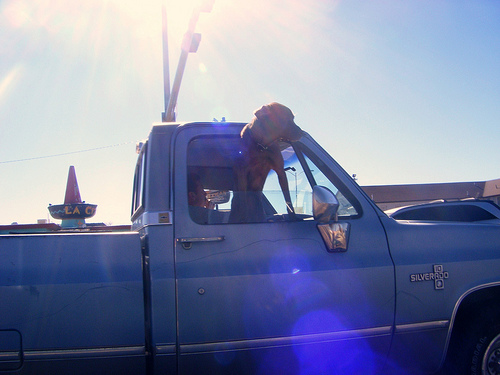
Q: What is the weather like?
A: It is cloudy.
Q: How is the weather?
A: It is cloudy.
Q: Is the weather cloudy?
A: Yes, it is cloudy.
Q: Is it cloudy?
A: Yes, it is cloudy.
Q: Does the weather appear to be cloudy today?
A: Yes, it is cloudy.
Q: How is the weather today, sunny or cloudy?
A: It is cloudy.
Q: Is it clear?
A: No, it is cloudy.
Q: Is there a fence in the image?
A: No, there are no fences.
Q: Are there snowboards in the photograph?
A: No, there are no snowboards.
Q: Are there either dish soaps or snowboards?
A: No, there are no snowboards or dish soaps.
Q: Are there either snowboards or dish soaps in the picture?
A: No, there are no snowboards or dish soaps.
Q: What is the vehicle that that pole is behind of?
A: The vehicle is a truck.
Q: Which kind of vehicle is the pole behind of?
A: The pole is behind the truck.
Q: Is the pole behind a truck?
A: Yes, the pole is behind a truck.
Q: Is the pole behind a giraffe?
A: No, the pole is behind a truck.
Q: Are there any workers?
A: No, there are no workers.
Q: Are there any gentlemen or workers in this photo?
A: No, there are no workers or gentlemen.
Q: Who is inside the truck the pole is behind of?
A: The driver is inside the truck.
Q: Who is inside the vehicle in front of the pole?
A: The driver is inside the truck.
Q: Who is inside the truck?
A: The driver is inside the truck.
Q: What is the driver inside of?
A: The driver is inside the truck.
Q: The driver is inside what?
A: The driver is inside the truck.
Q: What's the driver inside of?
A: The driver is inside the truck.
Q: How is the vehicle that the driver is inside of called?
A: The vehicle is a truck.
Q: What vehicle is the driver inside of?
A: The driver is inside the truck.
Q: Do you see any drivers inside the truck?
A: Yes, there is a driver inside the truck.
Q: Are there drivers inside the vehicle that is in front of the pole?
A: Yes, there is a driver inside the truck.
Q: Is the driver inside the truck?
A: Yes, the driver is inside the truck.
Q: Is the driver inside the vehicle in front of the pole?
A: Yes, the driver is inside the truck.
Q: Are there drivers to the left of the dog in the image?
A: Yes, there is a driver to the left of the dog.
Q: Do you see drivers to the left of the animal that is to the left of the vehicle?
A: Yes, there is a driver to the left of the dog.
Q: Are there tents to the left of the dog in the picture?
A: No, there is a driver to the left of the dog.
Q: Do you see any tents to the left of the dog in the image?
A: No, there is a driver to the left of the dog.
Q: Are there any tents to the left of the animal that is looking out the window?
A: No, there is a driver to the left of the dog.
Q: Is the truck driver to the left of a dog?
A: Yes, the driver is to the left of a dog.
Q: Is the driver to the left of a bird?
A: No, the driver is to the left of a dog.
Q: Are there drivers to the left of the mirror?
A: Yes, there is a driver to the left of the mirror.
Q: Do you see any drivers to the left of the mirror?
A: Yes, there is a driver to the left of the mirror.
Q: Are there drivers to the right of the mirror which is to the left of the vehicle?
A: No, the driver is to the left of the mirror.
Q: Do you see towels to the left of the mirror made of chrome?
A: No, there is a driver to the left of the mirror.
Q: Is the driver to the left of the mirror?
A: Yes, the driver is to the left of the mirror.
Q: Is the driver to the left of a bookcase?
A: No, the driver is to the left of the mirror.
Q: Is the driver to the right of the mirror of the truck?
A: No, the driver is to the left of the mirror.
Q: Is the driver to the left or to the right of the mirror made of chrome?
A: The driver is to the left of the mirror.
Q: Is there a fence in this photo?
A: No, there are no fences.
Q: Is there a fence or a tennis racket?
A: No, there are no fences or rackets.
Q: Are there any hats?
A: Yes, there is a hat.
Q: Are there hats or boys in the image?
A: Yes, there is a hat.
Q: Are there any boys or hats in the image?
A: Yes, there is a hat.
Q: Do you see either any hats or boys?
A: Yes, there is a hat.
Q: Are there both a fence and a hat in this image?
A: No, there is a hat but no fences.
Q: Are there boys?
A: No, there are no boys.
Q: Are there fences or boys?
A: No, there are no boys or fences.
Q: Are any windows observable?
A: Yes, there is a window.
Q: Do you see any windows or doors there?
A: Yes, there is a window.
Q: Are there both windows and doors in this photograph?
A: Yes, there are both a window and a door.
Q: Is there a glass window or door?
A: Yes, there is a glass window.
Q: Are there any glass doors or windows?
A: Yes, there is a glass window.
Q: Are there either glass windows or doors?
A: Yes, there is a glass window.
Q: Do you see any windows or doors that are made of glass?
A: Yes, the window is made of glass.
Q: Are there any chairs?
A: No, there are no chairs.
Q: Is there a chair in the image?
A: No, there are no chairs.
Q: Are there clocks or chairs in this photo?
A: No, there are no chairs or clocks.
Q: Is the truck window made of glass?
A: Yes, the window is made of glass.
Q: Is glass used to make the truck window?
A: Yes, the window is made of glass.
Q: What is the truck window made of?
A: The window is made of glass.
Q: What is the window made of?
A: The window is made of glass.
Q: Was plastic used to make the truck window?
A: No, the window is made of glass.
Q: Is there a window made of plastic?
A: No, there is a window but it is made of glass.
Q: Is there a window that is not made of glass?
A: No, there is a window but it is made of glass.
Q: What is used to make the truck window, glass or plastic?
A: The window is made of glass.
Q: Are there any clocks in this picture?
A: No, there are no clocks.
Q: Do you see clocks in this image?
A: No, there are no clocks.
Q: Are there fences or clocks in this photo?
A: No, there are no clocks or fences.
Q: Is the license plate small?
A: Yes, the license plate is small.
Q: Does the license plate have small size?
A: Yes, the license plate is small.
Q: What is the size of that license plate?
A: The license plate is small.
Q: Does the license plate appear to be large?
A: No, the license plate is small.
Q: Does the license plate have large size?
A: No, the license plate is small.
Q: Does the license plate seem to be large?
A: No, the license plate is small.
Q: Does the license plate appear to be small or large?
A: The license plate is small.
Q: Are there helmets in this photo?
A: No, there are no helmets.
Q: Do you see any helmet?
A: No, there are no helmets.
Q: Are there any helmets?
A: No, there are no helmets.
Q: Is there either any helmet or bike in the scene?
A: No, there are no helmets or bikes.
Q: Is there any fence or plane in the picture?
A: No, there are no fences or airplanes.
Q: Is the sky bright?
A: Yes, the sky is bright.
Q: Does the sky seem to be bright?
A: Yes, the sky is bright.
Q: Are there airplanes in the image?
A: No, there are no airplanes.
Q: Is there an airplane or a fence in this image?
A: No, there are no airplanes or fences.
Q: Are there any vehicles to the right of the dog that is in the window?
A: Yes, there is a vehicle to the right of the dog.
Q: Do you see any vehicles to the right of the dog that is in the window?
A: Yes, there is a vehicle to the right of the dog.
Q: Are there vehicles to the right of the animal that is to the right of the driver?
A: Yes, there is a vehicle to the right of the dog.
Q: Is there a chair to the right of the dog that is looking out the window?
A: No, there is a vehicle to the right of the dog.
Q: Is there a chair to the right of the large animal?
A: No, there is a vehicle to the right of the dog.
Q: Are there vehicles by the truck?
A: Yes, there is a vehicle by the truck.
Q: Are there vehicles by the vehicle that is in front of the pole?
A: Yes, there is a vehicle by the truck.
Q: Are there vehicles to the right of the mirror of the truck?
A: Yes, there is a vehicle to the right of the mirror.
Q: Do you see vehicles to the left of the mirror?
A: No, the vehicle is to the right of the mirror.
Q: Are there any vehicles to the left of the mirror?
A: No, the vehicle is to the right of the mirror.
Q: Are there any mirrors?
A: Yes, there is a mirror.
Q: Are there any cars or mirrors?
A: Yes, there is a mirror.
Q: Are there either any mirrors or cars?
A: Yes, there is a mirror.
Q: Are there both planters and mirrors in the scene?
A: No, there is a mirror but no planters.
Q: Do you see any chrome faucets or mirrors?
A: Yes, there is a chrome mirror.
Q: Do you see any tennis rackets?
A: No, there are no tennis rackets.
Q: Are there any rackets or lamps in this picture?
A: No, there are no rackets or lamps.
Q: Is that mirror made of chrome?
A: Yes, the mirror is made of chrome.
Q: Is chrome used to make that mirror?
A: Yes, the mirror is made of chrome.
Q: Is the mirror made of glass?
A: No, the mirror is made of chrome.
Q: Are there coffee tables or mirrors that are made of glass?
A: No, there is a mirror but it is made of chrome.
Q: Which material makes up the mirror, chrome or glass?
A: The mirror is made of chrome.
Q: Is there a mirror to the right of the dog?
A: Yes, there is a mirror to the right of the dog.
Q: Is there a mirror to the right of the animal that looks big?
A: Yes, there is a mirror to the right of the dog.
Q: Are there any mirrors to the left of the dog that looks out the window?
A: No, the mirror is to the right of the dog.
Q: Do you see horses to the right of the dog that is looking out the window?
A: No, there is a mirror to the right of the dog.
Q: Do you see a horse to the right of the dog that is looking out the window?
A: No, there is a mirror to the right of the dog.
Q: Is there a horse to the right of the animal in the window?
A: No, there is a mirror to the right of the dog.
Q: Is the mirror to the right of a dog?
A: Yes, the mirror is to the right of a dog.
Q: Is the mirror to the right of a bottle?
A: No, the mirror is to the right of a dog.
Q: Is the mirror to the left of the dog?
A: No, the mirror is to the right of the dog.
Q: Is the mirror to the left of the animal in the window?
A: No, the mirror is to the right of the dog.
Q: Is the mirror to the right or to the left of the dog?
A: The mirror is to the right of the dog.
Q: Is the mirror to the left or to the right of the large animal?
A: The mirror is to the right of the dog.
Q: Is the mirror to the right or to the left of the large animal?
A: The mirror is to the right of the dog.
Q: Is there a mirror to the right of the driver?
A: Yes, there is a mirror to the right of the driver.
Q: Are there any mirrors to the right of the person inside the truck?
A: Yes, there is a mirror to the right of the driver.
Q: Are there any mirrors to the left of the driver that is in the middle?
A: No, the mirror is to the right of the driver.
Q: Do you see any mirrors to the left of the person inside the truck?
A: No, the mirror is to the right of the driver.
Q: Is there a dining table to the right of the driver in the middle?
A: No, there is a mirror to the right of the driver.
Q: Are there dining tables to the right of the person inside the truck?
A: No, there is a mirror to the right of the driver.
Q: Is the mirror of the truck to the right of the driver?
A: Yes, the mirror is to the right of the driver.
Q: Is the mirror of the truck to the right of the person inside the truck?
A: Yes, the mirror is to the right of the driver.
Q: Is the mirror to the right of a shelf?
A: No, the mirror is to the right of the driver.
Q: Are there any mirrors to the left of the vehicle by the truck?
A: Yes, there is a mirror to the left of the vehicle.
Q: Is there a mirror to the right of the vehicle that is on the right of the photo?
A: No, the mirror is to the left of the vehicle.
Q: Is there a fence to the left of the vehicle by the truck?
A: No, there is a mirror to the left of the vehicle.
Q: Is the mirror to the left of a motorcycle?
A: No, the mirror is to the left of the vehicle.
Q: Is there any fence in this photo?
A: No, there are no fences.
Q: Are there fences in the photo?
A: No, there are no fences.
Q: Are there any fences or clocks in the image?
A: No, there are no fences or clocks.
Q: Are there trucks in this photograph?
A: Yes, there is a truck.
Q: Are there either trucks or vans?
A: Yes, there is a truck.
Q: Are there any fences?
A: No, there are no fences.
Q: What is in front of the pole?
A: The truck is in front of the pole.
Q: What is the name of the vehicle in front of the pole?
A: The vehicle is a truck.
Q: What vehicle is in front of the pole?
A: The vehicle is a truck.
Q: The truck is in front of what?
A: The truck is in front of the pole.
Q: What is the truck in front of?
A: The truck is in front of the pole.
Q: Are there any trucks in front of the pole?
A: Yes, there is a truck in front of the pole.